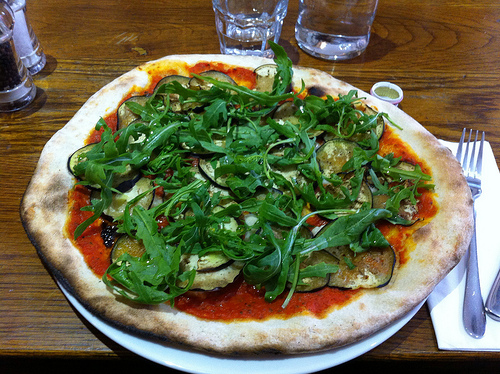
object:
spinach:
[258, 37, 295, 98]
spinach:
[287, 201, 393, 257]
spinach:
[368, 152, 433, 204]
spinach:
[122, 197, 183, 287]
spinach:
[91, 110, 123, 162]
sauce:
[216, 294, 270, 316]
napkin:
[424, 138, 500, 352]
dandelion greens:
[56, 38, 434, 312]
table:
[1, 0, 500, 360]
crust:
[20, 52, 474, 359]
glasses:
[210, 0, 287, 59]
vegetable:
[66, 40, 412, 308]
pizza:
[19, 51, 477, 352]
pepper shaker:
[0, 0, 45, 114]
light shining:
[461, 167, 485, 194]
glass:
[291, 0, 378, 61]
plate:
[51, 279, 426, 373]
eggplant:
[177, 257, 245, 296]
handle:
[482, 266, 500, 319]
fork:
[452, 127, 494, 337]